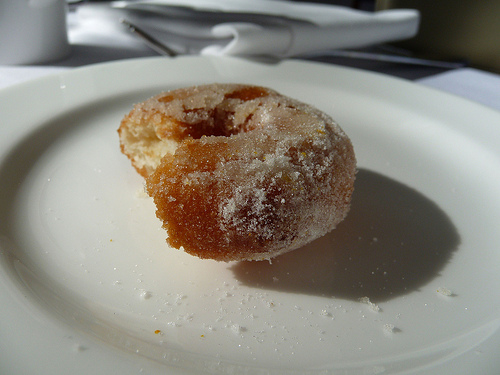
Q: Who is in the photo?
A: Nobody.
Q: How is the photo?
A: Clear.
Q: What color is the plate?
A: White.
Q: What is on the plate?
A: Donut.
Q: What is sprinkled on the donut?
A: Sugar.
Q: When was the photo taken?
A: Daytime.